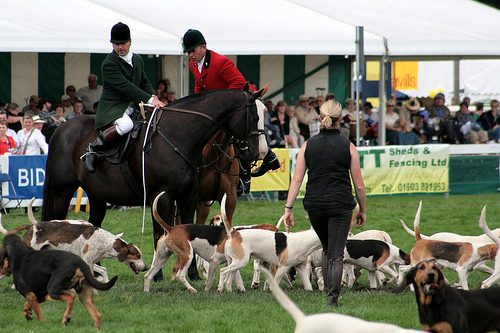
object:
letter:
[369, 148, 386, 168]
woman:
[284, 99, 367, 309]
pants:
[307, 205, 352, 299]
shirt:
[301, 127, 358, 211]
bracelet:
[285, 204, 294, 210]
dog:
[395, 261, 500, 333]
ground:
[0, 193, 500, 333]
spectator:
[477, 99, 500, 142]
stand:
[0, 0, 500, 212]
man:
[83, 21, 167, 174]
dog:
[0, 230, 124, 330]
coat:
[189, 49, 257, 93]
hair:
[319, 99, 342, 130]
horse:
[41, 82, 266, 284]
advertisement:
[242, 143, 450, 204]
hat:
[110, 22, 131, 44]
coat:
[94, 48, 157, 131]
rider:
[181, 28, 282, 177]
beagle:
[0, 211, 148, 295]